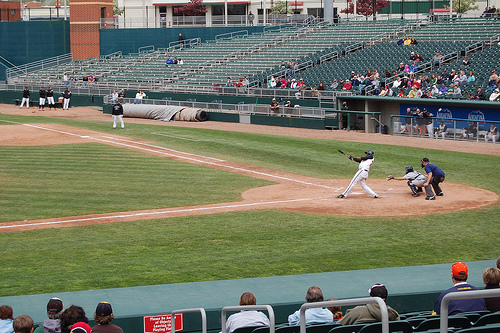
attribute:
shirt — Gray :
[404, 172, 423, 179]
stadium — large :
[94, 14, 431, 152]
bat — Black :
[337, 143, 349, 160]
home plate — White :
[349, 184, 369, 199]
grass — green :
[195, 233, 318, 272]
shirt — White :
[222, 304, 294, 326]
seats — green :
[264, 55, 454, 135]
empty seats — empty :
[203, 18, 499, 36]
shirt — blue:
[226, 300, 288, 331]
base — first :
[81, 127, 101, 149]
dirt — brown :
[269, 182, 305, 203]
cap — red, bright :
[451, 259, 470, 277]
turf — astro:
[82, 156, 191, 211]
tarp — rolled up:
[121, 101, 208, 121]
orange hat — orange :
[452, 260, 469, 279]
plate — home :
[350, 188, 362, 200]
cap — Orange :
[448, 258, 470, 277]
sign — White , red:
[141, 310, 184, 330]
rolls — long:
[97, 85, 202, 131]